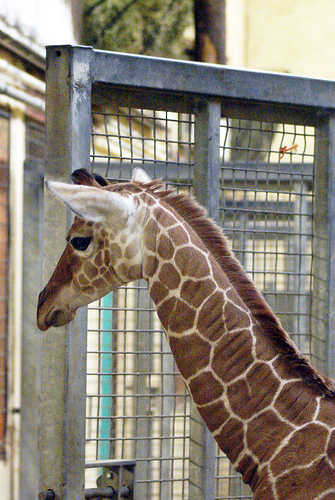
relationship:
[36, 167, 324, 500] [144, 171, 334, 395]
giraffe has hair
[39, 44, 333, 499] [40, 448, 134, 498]
gate has lock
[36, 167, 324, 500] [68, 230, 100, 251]
giraffe has eye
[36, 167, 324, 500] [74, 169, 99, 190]
giraffe has horn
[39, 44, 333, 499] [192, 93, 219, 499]
gate has bar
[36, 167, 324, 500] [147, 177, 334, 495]
giraffe has neck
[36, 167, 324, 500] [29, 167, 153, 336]
giraffe has head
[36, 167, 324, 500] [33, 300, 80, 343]
giraffe has mouth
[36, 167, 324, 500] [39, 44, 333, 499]
giraffe behind gate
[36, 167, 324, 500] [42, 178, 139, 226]
giraffe has ear